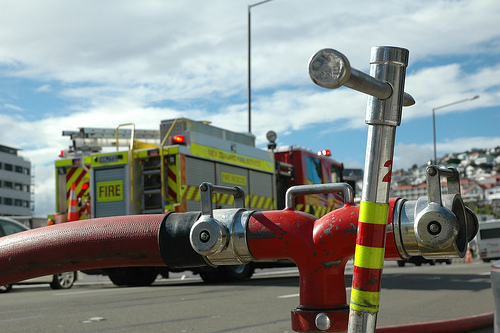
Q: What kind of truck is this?
A: A fire truck.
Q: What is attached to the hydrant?
A: A fire hose.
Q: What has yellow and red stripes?
A: Post in foreground.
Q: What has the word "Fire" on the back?
A: The fire truck.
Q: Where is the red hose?
A: Foreground and to the left.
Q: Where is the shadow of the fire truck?
A: On the right.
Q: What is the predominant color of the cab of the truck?
A: Red.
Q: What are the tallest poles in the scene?
A: Street light poles.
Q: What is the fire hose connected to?
A: Water supply.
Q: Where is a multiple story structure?
A: On the left.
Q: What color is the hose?
A: Red.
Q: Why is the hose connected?
A: Water.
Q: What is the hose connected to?
A: Hydrant.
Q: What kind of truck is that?
A: Fire.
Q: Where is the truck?
A: Street.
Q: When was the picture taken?
A: Daytime.